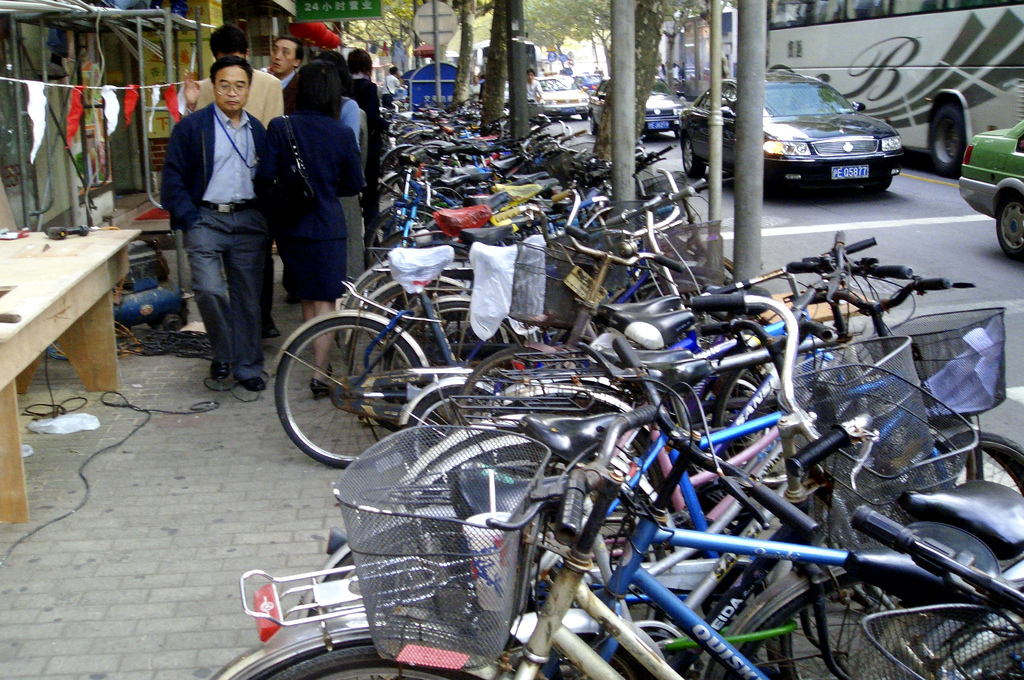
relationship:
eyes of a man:
[206, 75, 254, 94] [152, 46, 292, 398]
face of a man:
[209, 66, 248, 114] [152, 46, 292, 398]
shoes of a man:
[202, 359, 272, 407] [152, 46, 292, 398]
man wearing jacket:
[165, 45, 284, 413] [152, 102, 271, 245]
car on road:
[666, 42, 902, 214] [651, 128, 1021, 394]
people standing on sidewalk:
[148, 46, 386, 404] [7, 315, 447, 676]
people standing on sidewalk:
[152, 36, 302, 397] [7, 315, 447, 676]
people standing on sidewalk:
[256, 54, 382, 316] [7, 315, 447, 676]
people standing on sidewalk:
[273, 36, 390, 322] [7, 315, 447, 676]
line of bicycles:
[226, 60, 1006, 676] [363, 71, 1015, 676]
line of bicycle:
[226, 60, 1006, 676] [500, 395, 989, 677]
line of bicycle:
[226, 60, 1006, 676] [331, 265, 975, 657]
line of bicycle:
[226, 60, 1006, 676] [353, 224, 889, 568]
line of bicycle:
[226, 60, 1006, 676] [260, 192, 718, 488]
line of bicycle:
[226, 60, 1006, 676] [336, 166, 764, 424]